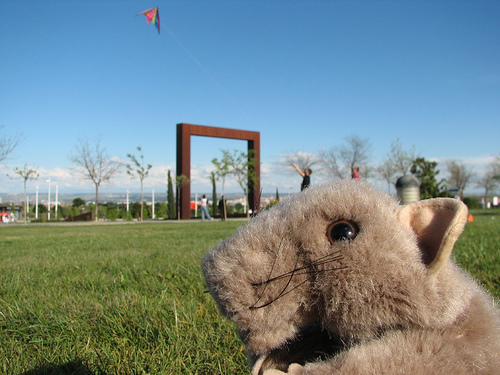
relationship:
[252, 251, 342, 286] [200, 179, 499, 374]
whisker of animal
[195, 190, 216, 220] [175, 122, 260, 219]
person by frame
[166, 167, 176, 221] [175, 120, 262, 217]
tree next to frame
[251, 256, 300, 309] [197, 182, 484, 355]
whisker are on mouse's face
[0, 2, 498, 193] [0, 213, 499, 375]
sky above field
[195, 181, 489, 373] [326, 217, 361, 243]
animal has eye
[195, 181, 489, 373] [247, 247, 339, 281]
animal has whisker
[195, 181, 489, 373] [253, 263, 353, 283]
animal has whisker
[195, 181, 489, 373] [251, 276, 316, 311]
animal has whisker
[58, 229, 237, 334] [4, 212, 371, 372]
grass on ground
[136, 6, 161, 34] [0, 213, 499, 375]
kite above field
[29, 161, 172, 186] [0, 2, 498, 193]
cloud in sky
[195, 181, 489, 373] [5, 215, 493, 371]
animal on grass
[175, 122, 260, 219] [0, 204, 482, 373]
frame above field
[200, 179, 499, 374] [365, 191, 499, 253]
animal has ear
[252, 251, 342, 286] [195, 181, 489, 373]
whisker are on animal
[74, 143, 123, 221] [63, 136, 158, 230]
bare trees behind bare trees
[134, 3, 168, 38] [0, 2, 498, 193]
kite in sky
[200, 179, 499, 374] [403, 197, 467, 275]
animal has ear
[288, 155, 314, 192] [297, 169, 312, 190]
man wearing top